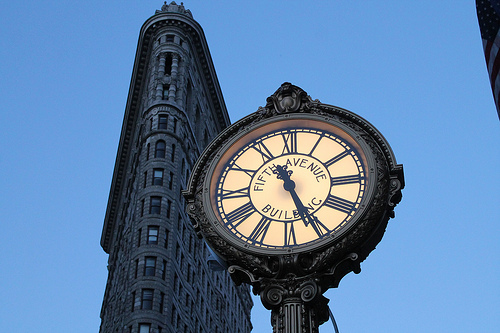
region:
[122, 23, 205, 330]
A tall black buidling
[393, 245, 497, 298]
A blue sky background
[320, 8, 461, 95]
A blue sky background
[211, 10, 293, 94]
A blue sky background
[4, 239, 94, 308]
A blue sky background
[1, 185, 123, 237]
A blue sky background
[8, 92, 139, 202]
A blue sky background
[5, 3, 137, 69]
A blue sky background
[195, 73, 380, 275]
clcok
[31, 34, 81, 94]
white clouds in blue sky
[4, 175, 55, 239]
white clouds in blue sky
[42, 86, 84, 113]
white clouds in blue sky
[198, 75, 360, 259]
black and white clock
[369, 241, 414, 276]
white clouds in blue sky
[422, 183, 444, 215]
white clouds in blue sky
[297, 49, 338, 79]
white clouds in blue sky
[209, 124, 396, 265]
this is a clock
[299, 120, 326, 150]
a number on a clock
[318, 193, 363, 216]
a number on a clock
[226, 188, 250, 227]
a number on a clock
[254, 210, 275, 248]
a number on a clock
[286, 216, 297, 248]
a number on a clock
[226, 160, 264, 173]
a number on a clock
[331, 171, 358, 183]
a number on a clock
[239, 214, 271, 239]
a number on a clock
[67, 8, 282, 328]
This is the flat iron building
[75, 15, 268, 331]
This building is flat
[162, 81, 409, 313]
This is a clock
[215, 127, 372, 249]
Clock's numbers are roman numerals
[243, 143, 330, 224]
Clock saids Fifth Avenue Building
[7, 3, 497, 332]
The sky is clear and blue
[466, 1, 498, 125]
The American flag is in the corner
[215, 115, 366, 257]
The clock's face is yellow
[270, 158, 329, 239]
The clock's hands are black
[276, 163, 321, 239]
Black hour and minute hands.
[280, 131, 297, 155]
Black XII on a clock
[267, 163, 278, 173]
Black H in FIFTH.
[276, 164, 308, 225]
A black hour hand.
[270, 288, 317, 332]
Black post under a clock.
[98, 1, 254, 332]
A curved large grey building.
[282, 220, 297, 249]
An upside down VI on a clock.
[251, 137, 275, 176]
roman numerals on a clock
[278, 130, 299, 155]
roman numerals on a clock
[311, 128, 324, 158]
roman numerals on a clock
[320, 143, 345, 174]
roman numerals on a clock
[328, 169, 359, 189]
roman numerals on a clock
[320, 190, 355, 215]
roman numerals on a clock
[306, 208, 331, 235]
roman numerals on a clock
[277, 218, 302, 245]
roman numerals on a clock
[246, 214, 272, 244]
roman numerals on a clock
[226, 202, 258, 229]
roman numerals on a clock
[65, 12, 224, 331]
large gray triangle building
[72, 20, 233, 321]
old gray triangle building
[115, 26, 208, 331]
large old triangle building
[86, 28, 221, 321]
triangle building standing int he grey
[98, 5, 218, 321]
old grey building